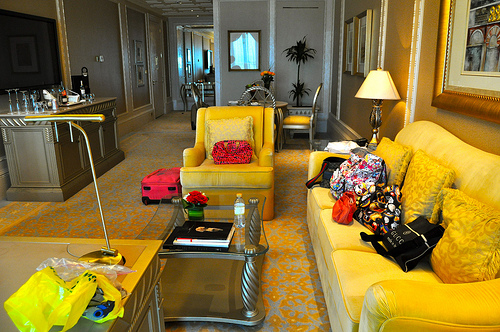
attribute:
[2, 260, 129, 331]
bag — yellow, plastic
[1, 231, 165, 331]
counter — yellow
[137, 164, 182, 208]
bag — pink, luggage, red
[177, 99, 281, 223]
chair — yellow, bright yellow, comfortable, comfy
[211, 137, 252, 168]
bag — pink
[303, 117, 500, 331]
couch — yellow, leather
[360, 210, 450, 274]
purses — black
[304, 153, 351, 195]
purses — red, black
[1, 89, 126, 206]
bar — in corner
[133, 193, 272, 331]
coffee table — glass, metal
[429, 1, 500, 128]
picture — large, golden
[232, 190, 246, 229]
bottle — water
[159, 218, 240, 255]
books — stacked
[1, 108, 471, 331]
floor — carpet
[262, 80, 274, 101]
vase — small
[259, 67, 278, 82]
flowers — orange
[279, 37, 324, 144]
plant — tropical, fake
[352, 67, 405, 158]
lamp — gold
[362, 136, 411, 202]
pillow — yello, yellow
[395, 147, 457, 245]
pillow — yellow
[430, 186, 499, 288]
pillow — yellow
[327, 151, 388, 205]
bag — floral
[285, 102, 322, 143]
pot — white